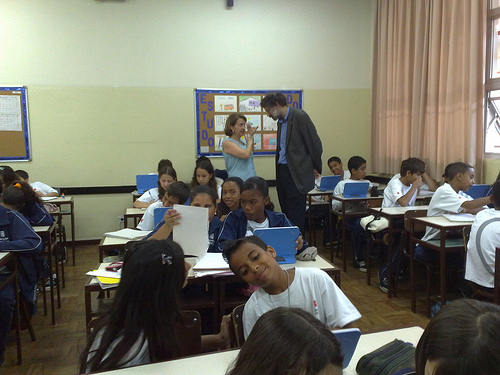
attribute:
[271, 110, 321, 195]
jacket — grey, suit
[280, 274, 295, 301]
necklace — silver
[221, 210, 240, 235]
jacket — blue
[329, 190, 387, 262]
table — blue, laptop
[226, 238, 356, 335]
boy — smiling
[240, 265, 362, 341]
shirt — white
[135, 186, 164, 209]
shirt — white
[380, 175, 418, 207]
shirt — white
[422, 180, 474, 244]
shirt — white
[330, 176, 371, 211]
shirt — white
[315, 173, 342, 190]
laptop — blue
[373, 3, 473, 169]
curtain — brown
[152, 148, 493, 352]
laptops — blue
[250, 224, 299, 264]
laptop computer — blue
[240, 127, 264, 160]
hand — girl's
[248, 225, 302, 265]
laptop — blue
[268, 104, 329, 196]
jacket — gray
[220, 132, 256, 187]
blouse — light blue